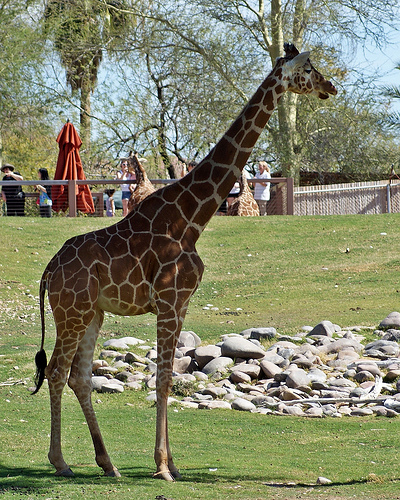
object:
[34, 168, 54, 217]
girl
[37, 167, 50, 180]
hair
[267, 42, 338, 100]
head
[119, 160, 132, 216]
person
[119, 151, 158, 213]
giraffe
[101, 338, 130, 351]
rocks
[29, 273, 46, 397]
tail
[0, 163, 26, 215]
man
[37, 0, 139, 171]
trees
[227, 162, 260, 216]
giraffe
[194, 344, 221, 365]
rocks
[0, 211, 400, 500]
ground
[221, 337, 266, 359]
rock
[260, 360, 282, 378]
rock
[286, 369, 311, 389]
rock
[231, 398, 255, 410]
rock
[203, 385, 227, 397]
rock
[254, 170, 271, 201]
shirt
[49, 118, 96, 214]
red umbrella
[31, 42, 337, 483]
giraffe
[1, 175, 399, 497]
fenced area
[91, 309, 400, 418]
rock pile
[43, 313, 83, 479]
legs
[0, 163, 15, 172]
hat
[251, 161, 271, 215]
person